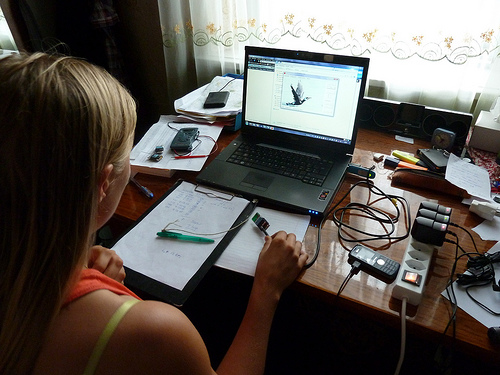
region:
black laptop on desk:
[186, 42, 382, 219]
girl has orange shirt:
[42, 263, 164, 314]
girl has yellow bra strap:
[80, 286, 175, 373]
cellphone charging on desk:
[332, 235, 397, 286]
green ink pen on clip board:
[150, 230, 227, 251]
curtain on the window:
[380, 36, 496, 103]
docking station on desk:
[362, 95, 472, 137]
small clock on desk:
[420, 122, 463, 152]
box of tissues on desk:
[465, 106, 495, 151]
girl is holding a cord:
[254, 212, 319, 272]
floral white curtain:
[154, 5, 499, 57]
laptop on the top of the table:
[197, 31, 321, 216]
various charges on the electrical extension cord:
[394, 179, 458, 326]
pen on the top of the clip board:
[143, 221, 230, 265]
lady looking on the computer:
[0, 51, 152, 243]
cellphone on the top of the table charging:
[328, 233, 397, 289]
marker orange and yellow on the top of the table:
[379, 117, 431, 182]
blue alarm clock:
[437, 112, 454, 152]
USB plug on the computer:
[345, 156, 377, 181]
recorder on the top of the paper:
[153, 102, 221, 174]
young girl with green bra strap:
[13, 40, 242, 374]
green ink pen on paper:
[147, 217, 237, 257]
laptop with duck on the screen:
[195, 50, 374, 199]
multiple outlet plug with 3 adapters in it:
[374, 146, 465, 340]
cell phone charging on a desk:
[333, 230, 410, 307]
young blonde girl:
[14, 28, 189, 365]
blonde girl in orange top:
[5, 58, 197, 373]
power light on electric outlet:
[392, 263, 437, 308]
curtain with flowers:
[177, 11, 499, 156]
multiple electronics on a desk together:
[125, 49, 447, 301]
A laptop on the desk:
[177, 40, 412, 287]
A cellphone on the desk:
[332, 239, 401, 288]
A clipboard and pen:
[134, 183, 266, 320]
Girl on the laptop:
[59, 53, 484, 232]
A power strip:
[409, 156, 439, 318]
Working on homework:
[159, 72, 449, 372]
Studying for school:
[21, 44, 473, 331]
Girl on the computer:
[66, 21, 263, 356]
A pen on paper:
[142, 226, 269, 286]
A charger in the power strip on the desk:
[403, 194, 495, 279]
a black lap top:
[194, 43, 370, 216]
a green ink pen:
[155, 226, 216, 244]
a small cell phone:
[346, 236, 398, 279]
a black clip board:
[91, 173, 260, 310]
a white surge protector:
[389, 189, 453, 374]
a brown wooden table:
[25, 68, 497, 367]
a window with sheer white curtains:
[155, 0, 498, 122]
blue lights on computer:
[307, 209, 319, 214]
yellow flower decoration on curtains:
[278, 13, 298, 26]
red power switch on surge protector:
[404, 268, 417, 282]